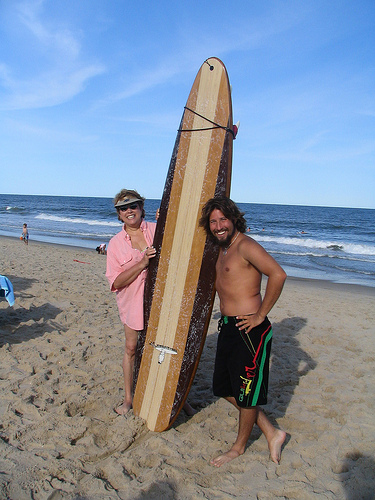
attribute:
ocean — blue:
[268, 207, 368, 252]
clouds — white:
[1, 4, 116, 147]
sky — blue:
[287, 84, 331, 122]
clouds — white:
[264, 39, 352, 94]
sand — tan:
[329, 313, 356, 358]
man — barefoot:
[179, 191, 296, 470]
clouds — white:
[16, 44, 82, 93]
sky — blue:
[99, 46, 156, 86]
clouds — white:
[53, 57, 101, 102]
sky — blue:
[245, 35, 320, 98]